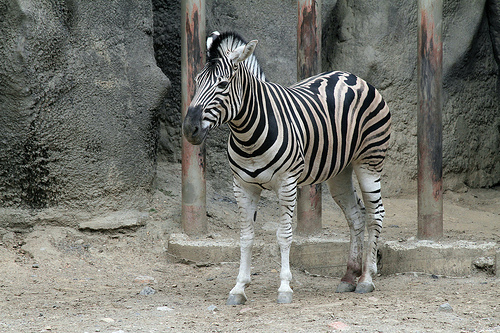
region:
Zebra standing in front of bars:
[180, 29, 391, 304]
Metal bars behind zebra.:
[165, 0, 495, 265]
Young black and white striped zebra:
[177, 30, 392, 305]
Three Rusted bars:
[170, 0, 446, 241]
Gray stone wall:
[0, 0, 495, 225]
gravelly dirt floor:
[2, 227, 492, 327]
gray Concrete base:
[170, 230, 497, 277]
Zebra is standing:
[180, 27, 390, 302]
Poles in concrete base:
[165, 0, 495, 275]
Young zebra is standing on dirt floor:
[175, 25, 398, 310]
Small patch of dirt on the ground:
[128, 312, 150, 323]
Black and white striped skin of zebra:
[307, 95, 338, 135]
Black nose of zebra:
[185, 116, 201, 148]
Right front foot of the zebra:
[233, 207, 252, 312]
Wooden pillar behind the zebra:
[416, 30, 448, 247]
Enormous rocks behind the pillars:
[76, 38, 116, 114]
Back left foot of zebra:
[365, 186, 387, 297]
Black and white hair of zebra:
[216, 33, 243, 50]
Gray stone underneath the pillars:
[417, 242, 473, 272]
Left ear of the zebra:
[241, 38, 258, 68]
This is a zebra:
[169, 28, 430, 291]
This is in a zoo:
[68, 34, 499, 263]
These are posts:
[401, 7, 461, 227]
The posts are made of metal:
[398, 18, 479, 246]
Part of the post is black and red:
[410, 30, 452, 230]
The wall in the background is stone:
[27, 31, 172, 213]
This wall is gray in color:
[12, 37, 150, 218]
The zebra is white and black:
[188, 60, 462, 326]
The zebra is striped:
[170, 57, 397, 204]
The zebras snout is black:
[179, 100, 214, 142]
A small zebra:
[186, 23, 408, 304]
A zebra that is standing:
[181, 24, 396, 308]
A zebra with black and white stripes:
[179, 30, 394, 309]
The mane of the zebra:
[207, 26, 272, 83]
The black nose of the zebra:
[179, 117, 203, 143]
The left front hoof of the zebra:
[276, 289, 296, 306]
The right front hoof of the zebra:
[223, 289, 249, 309]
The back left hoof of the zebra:
[357, 281, 374, 294]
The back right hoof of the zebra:
[330, 279, 355, 294]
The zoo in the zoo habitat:
[177, 27, 403, 324]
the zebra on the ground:
[165, 26, 410, 306]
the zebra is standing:
[177, 26, 426, 318]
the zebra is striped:
[158, 20, 460, 329]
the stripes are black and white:
[137, 7, 427, 293]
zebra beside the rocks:
[18, 20, 146, 179]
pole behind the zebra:
[163, 1, 236, 234]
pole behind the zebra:
[291, 7, 328, 236]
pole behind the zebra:
[413, 2, 455, 234]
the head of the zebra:
[164, 23, 251, 160]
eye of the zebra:
[208, 73, 238, 103]